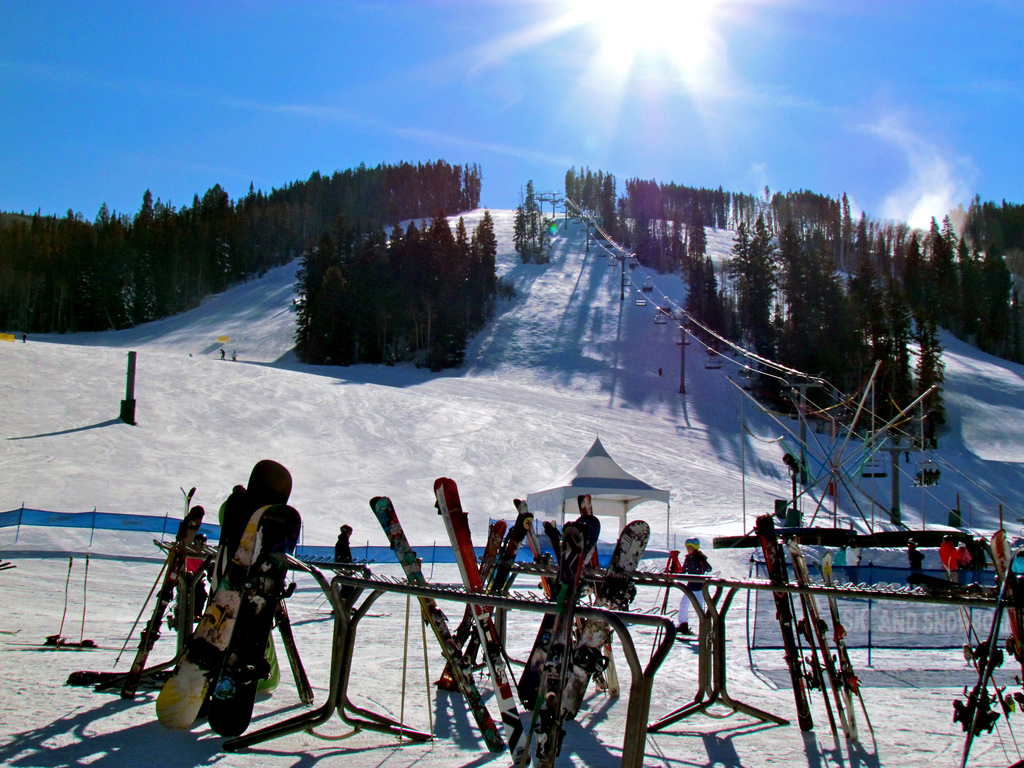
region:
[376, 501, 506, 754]
ski is in the snow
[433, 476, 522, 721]
ski is in the snow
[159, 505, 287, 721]
ski is in the snow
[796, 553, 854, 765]
ski is in the snow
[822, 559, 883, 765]
ski is in the snow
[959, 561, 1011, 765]
ski is in the snow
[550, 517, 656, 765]
ski is in the snow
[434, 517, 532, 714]
ski is in the snow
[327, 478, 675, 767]
skis and snowboards attached to a ski rack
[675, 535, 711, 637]
young person wearing a green and yellow helmet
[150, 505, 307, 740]
yellow snowboard next to black snowboard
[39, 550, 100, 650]
two ski poles next to each other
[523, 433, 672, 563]
white tent with blue stripes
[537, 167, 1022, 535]
group of trees next to ski lift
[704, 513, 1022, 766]
ski rack with several skis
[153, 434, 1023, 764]
a group of ski racks in front of a white tent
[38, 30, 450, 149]
Sky is blue color.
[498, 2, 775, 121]
Sun is shining brightly.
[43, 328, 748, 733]
Snow is in ground.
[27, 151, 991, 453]
Pine trees are green color.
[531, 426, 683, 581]
Tent is white and blue color.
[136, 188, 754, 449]
Shadow falls on snow.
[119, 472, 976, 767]
Skiing board and poles are arranged in stand.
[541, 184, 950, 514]
Cable car is above snow.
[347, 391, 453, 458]
Large body of snow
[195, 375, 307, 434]
Large body of snow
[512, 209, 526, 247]
A tree in a field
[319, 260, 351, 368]
A tree in a field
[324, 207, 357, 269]
A tree in a field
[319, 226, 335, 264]
A tree in a field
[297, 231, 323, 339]
A tree in a field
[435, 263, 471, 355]
A tree in a field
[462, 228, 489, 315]
A tree in a field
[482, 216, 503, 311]
A tree in a field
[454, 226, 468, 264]
A tree in a field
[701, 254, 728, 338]
A tree in a field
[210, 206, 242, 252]
green leaves on the tree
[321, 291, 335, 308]
green leaves on the tree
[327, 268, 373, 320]
green leaves on the tree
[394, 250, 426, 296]
green leaves on the tree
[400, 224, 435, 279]
green leaves on the tree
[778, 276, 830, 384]
green leaves on the tree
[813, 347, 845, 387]
green leaves on the tree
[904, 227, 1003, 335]
green leaves on the tree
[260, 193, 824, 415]
snow on a ski slope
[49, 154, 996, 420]
trees on the mountain side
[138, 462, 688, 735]
metal poles supporting skis and snowboards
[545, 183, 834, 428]
chairlift on the side of a mountain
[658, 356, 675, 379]
person on a mountain side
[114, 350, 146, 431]
a post in the snow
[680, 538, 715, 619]
a woman wearing white ski pants